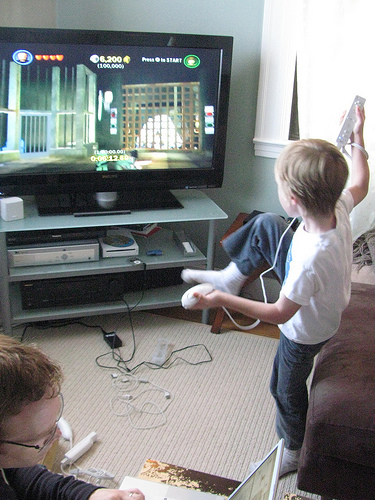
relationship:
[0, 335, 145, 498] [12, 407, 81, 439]
boy with glasses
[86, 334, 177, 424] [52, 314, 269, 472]
cord with rug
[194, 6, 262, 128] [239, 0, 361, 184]
walls with window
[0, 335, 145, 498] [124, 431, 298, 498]
boy with laptop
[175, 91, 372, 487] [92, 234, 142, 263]
boy playing video game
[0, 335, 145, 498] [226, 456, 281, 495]
boy looking at screen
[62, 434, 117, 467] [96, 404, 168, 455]
controller sitting on floor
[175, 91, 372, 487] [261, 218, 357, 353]
boy in t-shirt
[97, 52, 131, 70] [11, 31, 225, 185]
score on screen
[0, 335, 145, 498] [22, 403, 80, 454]
boy wearing glasses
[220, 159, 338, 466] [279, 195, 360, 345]
boy in t-shirt